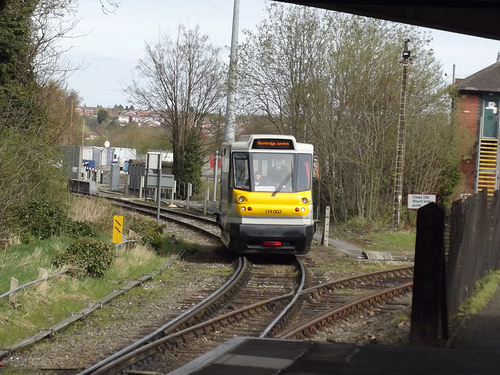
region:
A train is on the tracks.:
[157, 111, 362, 366]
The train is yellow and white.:
[182, 124, 343, 261]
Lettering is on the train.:
[243, 132, 303, 153]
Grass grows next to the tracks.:
[0, 230, 187, 356]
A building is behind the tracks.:
[443, 52, 498, 223]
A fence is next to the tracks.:
[395, 180, 499, 354]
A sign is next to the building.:
[392, 182, 448, 217]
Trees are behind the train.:
[249, 20, 447, 239]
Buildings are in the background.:
[68, 95, 268, 142]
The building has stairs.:
[469, 129, 499, 209]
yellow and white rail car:
[213, 125, 330, 265]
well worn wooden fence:
[416, 172, 498, 336]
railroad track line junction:
[188, 247, 407, 369]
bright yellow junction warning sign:
[107, 212, 127, 247]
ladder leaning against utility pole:
[392, 42, 408, 231]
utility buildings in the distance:
[67, 139, 219, 204]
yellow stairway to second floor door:
[473, 97, 499, 203]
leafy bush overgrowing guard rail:
[8, 233, 145, 312]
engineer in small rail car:
[266, 151, 293, 193]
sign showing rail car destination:
[251, 137, 297, 148]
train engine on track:
[217, 135, 322, 267]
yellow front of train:
[233, 186, 312, 223]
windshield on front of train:
[235, 149, 310, 194]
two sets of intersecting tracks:
[203, 276, 357, 331]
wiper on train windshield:
[275, 165, 300, 197]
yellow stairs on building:
[472, 138, 497, 188]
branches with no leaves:
[136, 33, 188, 107]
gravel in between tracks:
[165, 210, 207, 233]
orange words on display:
[248, 134, 300, 152]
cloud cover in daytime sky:
[122, 7, 165, 31]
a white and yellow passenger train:
[222, 129, 318, 253]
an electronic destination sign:
[254, 138, 292, 148]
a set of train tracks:
[94, 259, 410, 373]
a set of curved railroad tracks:
[86, 191, 307, 372]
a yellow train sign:
[109, 212, 124, 262]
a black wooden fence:
[417, 189, 499, 339]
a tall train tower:
[396, 39, 411, 226]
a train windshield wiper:
[268, 171, 291, 198]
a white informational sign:
[405, 192, 437, 209]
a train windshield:
[233, 153, 310, 192]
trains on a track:
[106, 132, 342, 246]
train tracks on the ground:
[174, 260, 394, 335]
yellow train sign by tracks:
[105, 204, 132, 252]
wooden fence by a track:
[417, 190, 489, 347]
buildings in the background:
[88, 105, 188, 151]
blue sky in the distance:
[88, 60, 123, 100]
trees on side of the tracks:
[3, 61, 80, 253]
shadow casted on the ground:
[314, 341, 461, 373]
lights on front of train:
[235, 192, 256, 220]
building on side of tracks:
[438, 60, 495, 214]